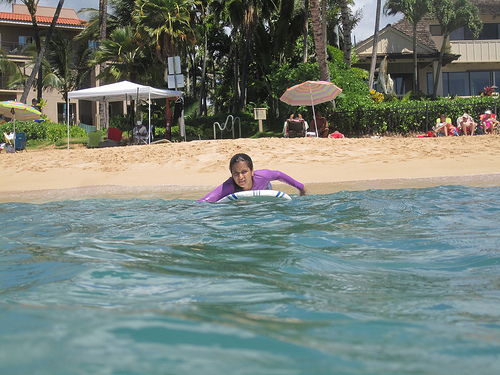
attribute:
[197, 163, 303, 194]
wetsuit — purple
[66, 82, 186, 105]
awning — white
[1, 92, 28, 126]
umbrella — orange, striped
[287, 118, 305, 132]
chair — pink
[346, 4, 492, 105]
house — big, beautiful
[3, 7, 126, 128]
house — orange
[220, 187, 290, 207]
board — blue, white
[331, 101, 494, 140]
bushes — green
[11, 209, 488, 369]
water — blue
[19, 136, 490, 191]
beach — vibrant, brown, sandy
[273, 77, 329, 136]
umbrella — pink, striped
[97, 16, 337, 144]
palms — green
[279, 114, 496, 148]
people — sitting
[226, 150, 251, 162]
hair — brown, pulled back